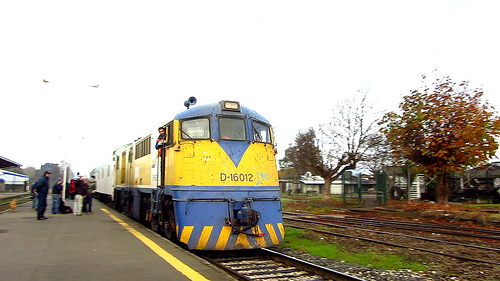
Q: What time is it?
A: Daytime.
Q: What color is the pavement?
A: Black.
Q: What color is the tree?
A: Orange and green.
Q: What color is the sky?
A: White.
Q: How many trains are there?
A: One.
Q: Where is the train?
A: At a train stop.